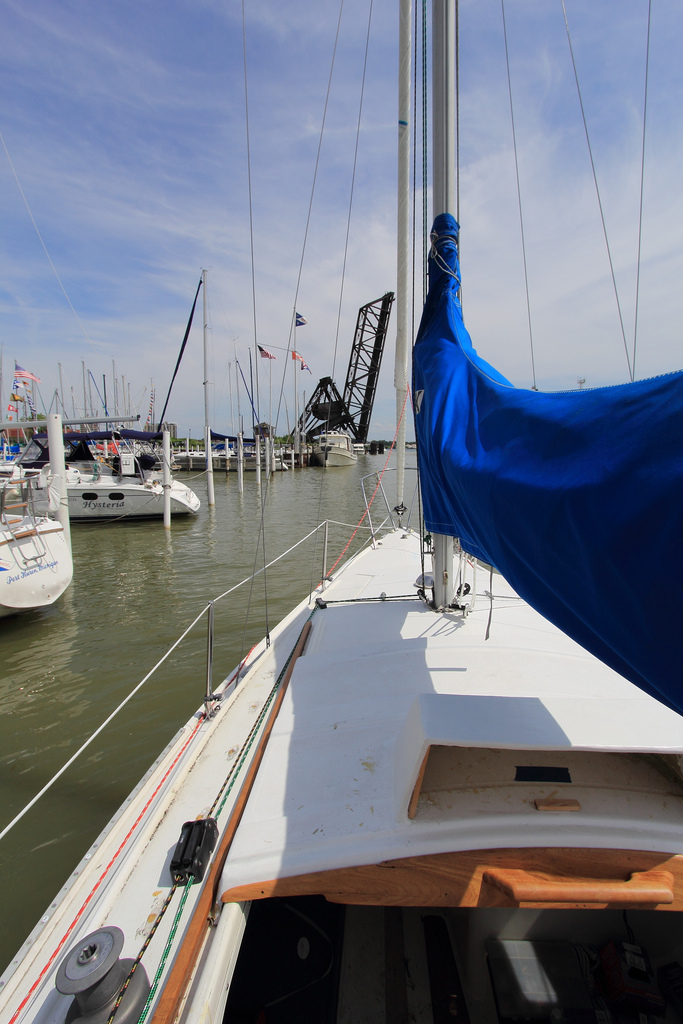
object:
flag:
[257, 342, 277, 363]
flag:
[291, 348, 305, 364]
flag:
[300, 358, 313, 378]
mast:
[291, 326, 300, 454]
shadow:
[270, 592, 683, 865]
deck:
[0, 515, 682, 1024]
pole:
[204, 603, 217, 712]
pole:
[261, 566, 273, 635]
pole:
[429, 532, 455, 615]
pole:
[389, 1, 417, 526]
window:
[80, 488, 101, 504]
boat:
[39, 457, 201, 524]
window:
[107, 489, 127, 503]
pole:
[45, 404, 75, 555]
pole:
[160, 427, 173, 532]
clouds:
[0, 6, 682, 453]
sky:
[0, 3, 683, 483]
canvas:
[403, 207, 683, 731]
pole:
[417, 2, 467, 610]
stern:
[0, 506, 77, 611]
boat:
[0, 510, 80, 613]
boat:
[312, 428, 359, 469]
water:
[0, 467, 405, 979]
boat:
[3, 3, 683, 1022]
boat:
[171, 439, 289, 473]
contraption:
[165, 807, 218, 891]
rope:
[100, 613, 316, 1020]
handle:
[479, 866, 678, 955]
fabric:
[401, 203, 683, 720]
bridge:
[337, 289, 397, 452]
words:
[82, 499, 127, 511]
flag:
[293, 310, 310, 328]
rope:
[292, 328, 300, 443]